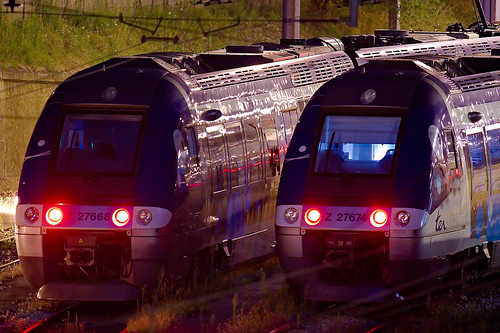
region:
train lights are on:
[17, 201, 390, 241]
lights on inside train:
[314, 135, 391, 177]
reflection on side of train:
[173, 84, 332, 253]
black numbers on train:
[65, 201, 137, 233]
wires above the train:
[0, 3, 353, 73]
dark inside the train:
[61, 115, 137, 177]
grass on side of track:
[0, 1, 492, 239]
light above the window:
[353, 81, 400, 119]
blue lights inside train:
[332, 136, 397, 168]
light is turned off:
[129, 208, 161, 235]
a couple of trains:
[16, 24, 499, 306]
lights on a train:
[303, 211, 392, 230]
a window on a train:
[303, 105, 403, 180]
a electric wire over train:
[0, 9, 355, 45]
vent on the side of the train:
[273, 50, 330, 84]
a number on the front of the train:
[317, 211, 372, 227]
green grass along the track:
[131, 285, 206, 332]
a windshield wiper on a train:
[322, 127, 340, 182]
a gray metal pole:
[278, 2, 305, 45]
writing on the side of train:
[429, 208, 454, 244]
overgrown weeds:
[120, 275, 299, 330]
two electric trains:
[11, 22, 498, 331]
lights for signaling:
[25, 205, 412, 227]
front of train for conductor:
[11, 59, 476, 251]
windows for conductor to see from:
[55, 104, 405, 180]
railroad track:
[36, 304, 398, 331]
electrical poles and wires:
[0, 2, 303, 37]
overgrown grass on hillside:
[9, 20, 80, 52]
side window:
[441, 123, 458, 157]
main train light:
[361, 87, 378, 104]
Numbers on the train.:
[76, 201, 119, 231]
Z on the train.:
[310, 207, 338, 229]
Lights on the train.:
[301, 203, 388, 233]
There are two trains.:
[35, 4, 497, 289]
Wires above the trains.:
[6, 2, 394, 77]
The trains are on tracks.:
[14, 293, 441, 332]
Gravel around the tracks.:
[323, 273, 498, 332]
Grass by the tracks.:
[207, 290, 315, 327]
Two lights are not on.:
[8, 198, 164, 227]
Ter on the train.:
[430, 202, 458, 246]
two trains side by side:
[15, 74, 487, 274]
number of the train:
[313, 201, 380, 248]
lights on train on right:
[27, 196, 141, 233]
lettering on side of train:
[427, 216, 464, 243]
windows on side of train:
[457, 136, 499, 206]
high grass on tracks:
[137, 277, 237, 319]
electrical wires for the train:
[3, 1, 287, 57]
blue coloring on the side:
[198, 144, 257, 260]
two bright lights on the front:
[304, 204, 389, 239]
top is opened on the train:
[152, 52, 252, 74]